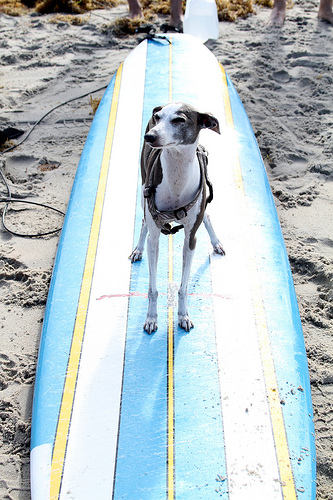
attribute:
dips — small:
[2, 143, 66, 206]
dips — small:
[275, 153, 310, 194]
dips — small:
[289, 246, 317, 319]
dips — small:
[27, 30, 61, 78]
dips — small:
[5, 357, 28, 393]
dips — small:
[45, 139, 72, 183]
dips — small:
[5, 259, 39, 312]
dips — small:
[279, 143, 314, 219]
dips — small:
[290, 220, 300, 275]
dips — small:
[301, 245, 322, 284]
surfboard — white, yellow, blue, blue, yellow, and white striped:
[26, 33, 320, 497]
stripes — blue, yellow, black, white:
[25, 317, 314, 479]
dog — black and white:
[111, 98, 239, 362]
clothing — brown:
[139, 120, 217, 248]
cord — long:
[2, 71, 120, 256]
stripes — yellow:
[48, 62, 123, 497]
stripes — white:
[60, 36, 147, 497]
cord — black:
[0, 84, 107, 243]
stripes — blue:
[25, 67, 115, 453]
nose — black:
[141, 128, 157, 144]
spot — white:
[155, 102, 186, 147]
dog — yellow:
[126, 100, 228, 336]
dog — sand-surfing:
[128, 115, 233, 265]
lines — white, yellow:
[84, 65, 146, 460]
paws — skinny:
[132, 300, 257, 340]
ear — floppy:
[191, 86, 241, 150]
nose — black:
[141, 115, 162, 134]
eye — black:
[161, 111, 195, 126]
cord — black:
[9, 65, 98, 284]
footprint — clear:
[300, 384, 331, 453]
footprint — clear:
[271, 236, 331, 320]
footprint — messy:
[263, 137, 328, 207]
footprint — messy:
[244, 35, 288, 90]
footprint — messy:
[4, 331, 39, 384]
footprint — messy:
[6, 133, 67, 221]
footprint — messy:
[0, 252, 43, 305]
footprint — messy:
[0, 343, 37, 384]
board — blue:
[24, 28, 321, 497]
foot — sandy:
[265, 5, 295, 29]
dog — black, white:
[122, 96, 236, 277]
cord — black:
[0, 84, 84, 278]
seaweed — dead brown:
[0, 1, 120, 19]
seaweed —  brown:
[2, 1, 278, 19]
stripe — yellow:
[160, 285, 187, 495]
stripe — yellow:
[163, 61, 178, 495]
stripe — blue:
[175, 282, 229, 497]